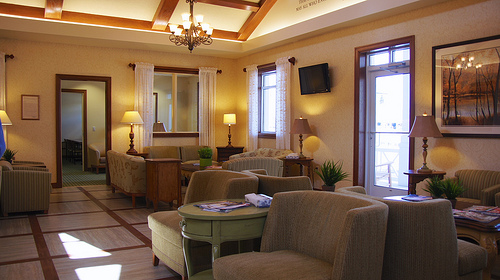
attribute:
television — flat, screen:
[289, 53, 335, 97]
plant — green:
[423, 173, 445, 208]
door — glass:
[369, 42, 413, 194]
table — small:
[176, 195, 264, 245]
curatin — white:
[133, 61, 154, 153]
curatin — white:
[196, 65, 216, 165]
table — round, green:
[179, 191, 276, 278]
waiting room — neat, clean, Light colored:
[2, 2, 499, 278]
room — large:
[1, 1, 491, 278]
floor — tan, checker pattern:
[0, 182, 185, 278]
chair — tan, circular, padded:
[217, 178, 394, 279]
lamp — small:
[120, 110, 144, 155]